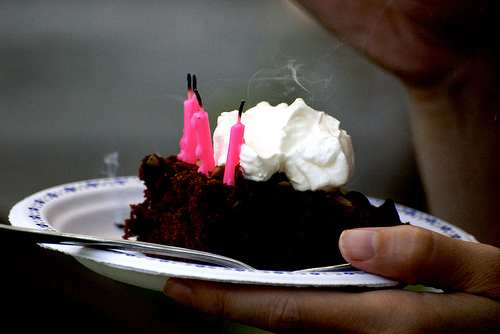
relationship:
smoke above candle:
[173, 14, 382, 137] [216, 91, 258, 184]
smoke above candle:
[173, 14, 382, 137] [186, 89, 229, 184]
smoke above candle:
[173, 14, 382, 137] [170, 69, 200, 159]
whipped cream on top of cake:
[227, 84, 357, 194] [134, 132, 341, 262]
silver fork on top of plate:
[5, 216, 376, 293] [29, 141, 499, 323]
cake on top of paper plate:
[112, 67, 414, 274] [8, 172, 494, 289]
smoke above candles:
[173, 14, 382, 137] [223, 89, 253, 186]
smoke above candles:
[173, 14, 382, 137] [188, 81, 220, 173]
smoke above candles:
[173, 14, 382, 137] [169, 58, 201, 167]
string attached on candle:
[234, 97, 249, 119] [225, 119, 247, 184]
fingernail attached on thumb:
[340, 226, 383, 262] [336, 222, 498, 293]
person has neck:
[163, 0, 498, 332] [399, 84, 499, 247]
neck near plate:
[399, 84, 499, 247] [6, 167, 477, 287]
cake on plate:
[118, 94, 405, 259] [6, 167, 477, 287]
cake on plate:
[112, 67, 414, 274] [6, 166, 486, 299]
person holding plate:
[163, 0, 498, 332] [6, 167, 477, 287]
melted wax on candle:
[172, 132, 186, 159] [180, 68, 196, 165]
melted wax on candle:
[172, 132, 186, 159] [221, 96, 245, 183]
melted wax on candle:
[172, 132, 186, 159] [191, 87, 214, 174]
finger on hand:
[163, 270, 465, 332] [153, 220, 499, 331]